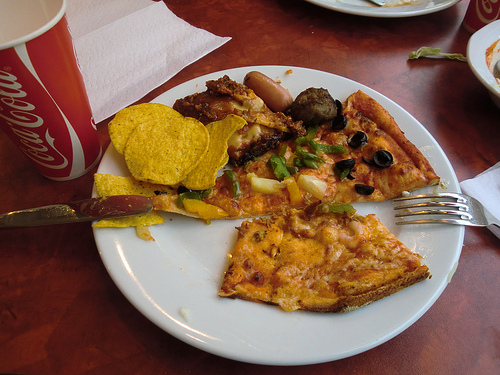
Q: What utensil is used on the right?
A: A fork.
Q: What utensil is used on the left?
A: A knife.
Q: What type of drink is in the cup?
A: Soda.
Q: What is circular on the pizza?
A: Black olives.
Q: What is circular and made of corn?
A: Tortilla chips.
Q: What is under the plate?
A: A table.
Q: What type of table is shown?
A: A marble table.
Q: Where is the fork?
A: Resting on the white plate.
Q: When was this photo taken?
A: During a meal.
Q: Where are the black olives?
A: On the pizza.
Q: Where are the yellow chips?
A: On the white plate.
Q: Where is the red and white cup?
A: To the left of the plate.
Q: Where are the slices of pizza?
A: On the white plate.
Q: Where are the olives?
A: On the pizza.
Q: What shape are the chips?
A: Round.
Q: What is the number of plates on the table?
A: 3.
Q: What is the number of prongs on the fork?
A: 4.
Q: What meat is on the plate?
A: Mini frank.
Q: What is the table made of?
A: Formica.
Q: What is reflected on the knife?
A: Coke cup.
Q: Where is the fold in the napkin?
A: Middle.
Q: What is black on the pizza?
A: Olives.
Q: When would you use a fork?
A: At dinner to eat with.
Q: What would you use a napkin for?
A: To wipe up spills and your mouth.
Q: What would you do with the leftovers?
A: You would box them up and take them home.